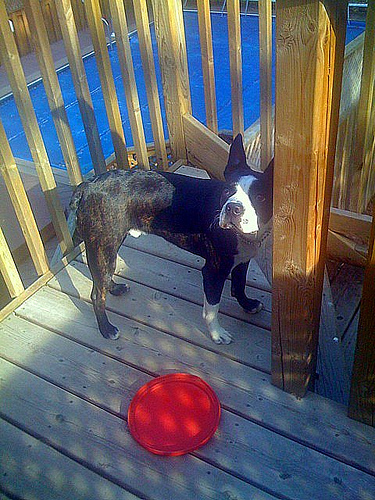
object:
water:
[7, 78, 85, 147]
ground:
[1, 154, 373, 497]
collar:
[231, 230, 272, 248]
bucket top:
[127, 373, 221, 457]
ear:
[224, 133, 252, 182]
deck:
[0, 159, 373, 499]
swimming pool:
[0, 5, 274, 192]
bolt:
[332, 336, 340, 345]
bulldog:
[69, 133, 274, 347]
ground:
[291, 112, 327, 147]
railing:
[183, 0, 375, 210]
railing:
[0, 1, 193, 312]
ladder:
[100, 18, 116, 51]